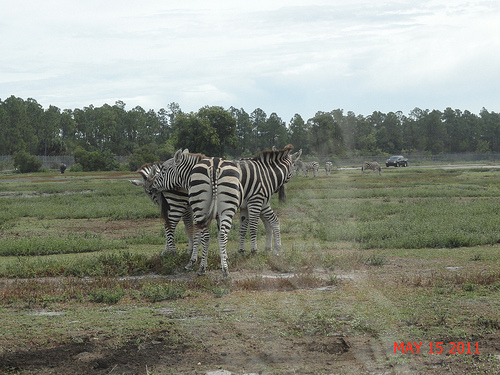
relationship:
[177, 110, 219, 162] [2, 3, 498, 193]
tree in background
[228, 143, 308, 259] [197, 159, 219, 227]
zebra has tail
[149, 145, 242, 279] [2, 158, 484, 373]
zebra standing in field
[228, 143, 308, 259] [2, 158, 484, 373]
zebra standing in field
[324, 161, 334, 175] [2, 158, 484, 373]
animal standing in field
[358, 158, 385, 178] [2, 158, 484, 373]
zebra standing in field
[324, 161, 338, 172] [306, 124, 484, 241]
animal in field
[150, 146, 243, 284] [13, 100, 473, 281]
zebra in field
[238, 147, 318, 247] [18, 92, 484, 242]
zebra in field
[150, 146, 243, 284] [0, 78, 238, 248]
zebra in field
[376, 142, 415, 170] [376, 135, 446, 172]
car in parking lot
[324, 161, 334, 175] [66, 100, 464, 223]
animal in field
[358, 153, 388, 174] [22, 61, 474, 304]
zebra in field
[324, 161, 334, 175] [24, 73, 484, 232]
animal in field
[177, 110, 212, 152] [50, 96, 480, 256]
tree in field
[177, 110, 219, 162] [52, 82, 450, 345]
tree in field